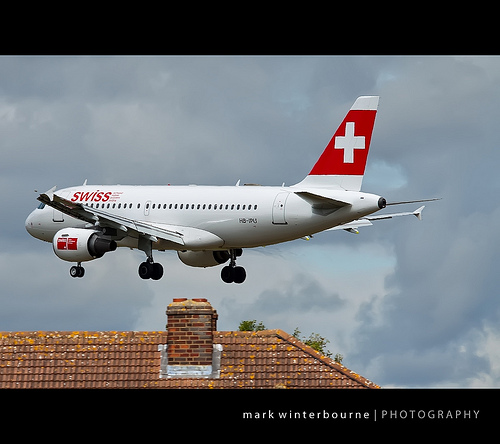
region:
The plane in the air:
[19, 88, 442, 285]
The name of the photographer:
[238, 406, 373, 423]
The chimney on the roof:
[151, 293, 224, 381]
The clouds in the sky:
[0, 53, 499, 388]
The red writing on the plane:
[68, 186, 120, 208]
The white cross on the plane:
[330, 118, 366, 167]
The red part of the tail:
[306, 107, 377, 174]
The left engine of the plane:
[48, 224, 115, 264]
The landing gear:
[68, 251, 250, 286]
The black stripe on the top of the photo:
[1, 1, 498, 53]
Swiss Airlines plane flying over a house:
[1, 56, 492, 387]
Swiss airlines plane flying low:
[23, 88, 448, 288]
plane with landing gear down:
[23, 91, 447, 296]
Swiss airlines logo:
[297, 86, 392, 187]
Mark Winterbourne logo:
[237, 404, 374, 428]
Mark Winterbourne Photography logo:
[236, 406, 484, 425]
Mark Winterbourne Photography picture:
[0, 47, 497, 442]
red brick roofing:
[0, 291, 394, 387]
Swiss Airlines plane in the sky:
[16, 90, 456, 295]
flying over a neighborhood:
[0, 67, 497, 384]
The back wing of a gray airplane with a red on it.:
[289, 94, 381, 189]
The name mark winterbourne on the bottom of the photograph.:
[237, 408, 372, 421]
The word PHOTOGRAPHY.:
[380, 408, 481, 421]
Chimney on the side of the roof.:
[162, 292, 217, 372]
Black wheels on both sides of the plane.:
[137, 259, 248, 285]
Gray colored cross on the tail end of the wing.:
[333, 121, 366, 163]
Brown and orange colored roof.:
[2, 327, 386, 390]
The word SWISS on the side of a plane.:
[71, 186, 113, 203]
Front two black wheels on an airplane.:
[66, 265, 86, 277]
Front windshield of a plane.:
[36, 197, 47, 209]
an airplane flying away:
[22, 93, 444, 296]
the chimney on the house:
[168, 295, 217, 361]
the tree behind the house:
[239, 316, 341, 357]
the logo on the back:
[332, 118, 364, 164]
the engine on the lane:
[43, 221, 108, 267]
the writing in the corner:
[239, 402, 481, 422]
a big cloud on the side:
[383, 118, 488, 368]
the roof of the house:
[1, 333, 351, 388]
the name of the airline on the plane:
[66, 187, 121, 202]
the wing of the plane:
[33, 187, 210, 257]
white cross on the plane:
[327, 115, 374, 172]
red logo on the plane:
[67, 190, 124, 206]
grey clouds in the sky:
[37, 73, 297, 153]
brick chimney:
[153, 293, 223, 365]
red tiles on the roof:
[20, 337, 137, 382]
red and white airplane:
[23, 70, 448, 305]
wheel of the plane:
[217, 263, 259, 291]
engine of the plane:
[44, 218, 124, 283]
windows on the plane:
[163, 196, 258, 218]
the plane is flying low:
[20, 114, 453, 251]